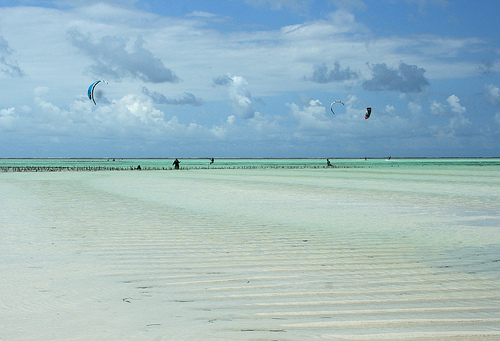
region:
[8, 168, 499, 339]
Large area of sand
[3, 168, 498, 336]
A large beach front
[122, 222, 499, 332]
Sand ripples from the wind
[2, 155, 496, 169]
The expanse of the ocean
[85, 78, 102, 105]
A large parasail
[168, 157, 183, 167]
A person on the beach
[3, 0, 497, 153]
A sky full of clouds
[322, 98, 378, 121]
Two parasals over the beach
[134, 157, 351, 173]
People on the beach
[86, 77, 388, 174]
People on the beach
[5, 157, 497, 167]
clear green water from a island beach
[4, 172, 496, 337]
large area of white sands on a island beach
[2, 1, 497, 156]
large area of blue sky over the beach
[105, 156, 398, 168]
people scattered out on the beach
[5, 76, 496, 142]
large clouds over the water of a island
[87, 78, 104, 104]
para kite pulling person in water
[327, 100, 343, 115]
para kite bending against the wind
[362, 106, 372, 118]
black and read para kite in the air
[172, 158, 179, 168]
one person watching para kite skiers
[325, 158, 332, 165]
person running along the beach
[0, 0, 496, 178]
dark blue sky with rolling clouds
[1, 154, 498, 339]
ripples in sand on beach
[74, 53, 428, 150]
2 parasailers in the sky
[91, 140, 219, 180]
person standing on beach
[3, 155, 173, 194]
rocks on path to water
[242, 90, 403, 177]
person flying kite on beach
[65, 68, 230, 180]
2 people flying 2 kites on beach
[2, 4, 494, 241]
clouds rolling on ocean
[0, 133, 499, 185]
aqua green blue water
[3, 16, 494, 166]
clouds rolling in over ocean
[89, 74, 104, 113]
A blue curved kite in the sky.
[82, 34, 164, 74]
The clouds in the sky are blue.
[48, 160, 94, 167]
The water in the background is green.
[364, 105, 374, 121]
The kite in the sky is black and red.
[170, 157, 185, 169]
The person standing is wearing black.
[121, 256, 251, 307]
The sand in the forefront is white.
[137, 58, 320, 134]
There are many clouds in the sky.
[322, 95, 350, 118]
The kite in the sky is curved.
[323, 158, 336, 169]
The person in the background is wearing black.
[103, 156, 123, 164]
There are two people the background.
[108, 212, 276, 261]
Beach in the photo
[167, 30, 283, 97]
Clouds in the photo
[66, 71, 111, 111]
A kite in the air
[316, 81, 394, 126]
A kite in the photo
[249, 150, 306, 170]
Ocean waters in the photo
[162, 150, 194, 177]
A person standing near the ocean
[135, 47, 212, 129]
White clouds in the photo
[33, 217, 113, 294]
Sand at the beach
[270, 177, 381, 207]
Beach at the coastline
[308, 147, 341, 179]
A person running